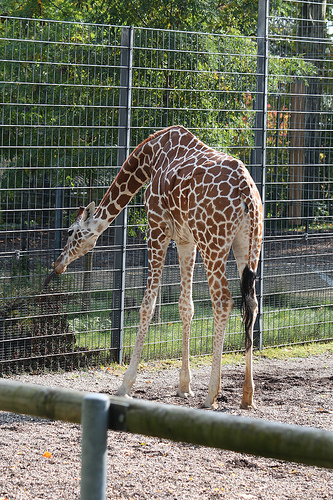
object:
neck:
[96, 130, 154, 225]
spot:
[169, 176, 177, 187]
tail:
[238, 188, 262, 356]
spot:
[123, 152, 139, 175]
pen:
[0, 1, 332, 377]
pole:
[0, 374, 332, 468]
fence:
[95, 23, 248, 93]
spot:
[75, 239, 83, 244]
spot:
[81, 230, 88, 238]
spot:
[107, 214, 115, 224]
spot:
[101, 208, 108, 220]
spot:
[105, 202, 119, 216]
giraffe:
[43, 116, 268, 410]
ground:
[0, 441, 329, 494]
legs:
[114, 227, 169, 395]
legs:
[176, 240, 195, 398]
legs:
[199, 248, 235, 410]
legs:
[233, 240, 260, 409]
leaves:
[48, 93, 93, 114]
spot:
[238, 179, 248, 188]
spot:
[204, 173, 212, 182]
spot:
[128, 175, 140, 190]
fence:
[0, 2, 319, 377]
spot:
[209, 207, 230, 222]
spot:
[212, 193, 232, 211]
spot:
[147, 192, 162, 216]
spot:
[161, 143, 182, 164]